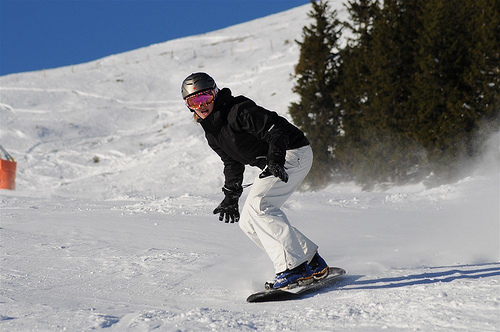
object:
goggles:
[186, 87, 215, 109]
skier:
[179, 71, 346, 303]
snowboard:
[244, 266, 345, 303]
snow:
[2, 2, 499, 329]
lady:
[180, 72, 328, 291]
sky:
[1, 0, 241, 61]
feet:
[265, 270, 315, 290]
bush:
[290, 0, 500, 192]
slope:
[2, 0, 497, 328]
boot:
[264, 261, 312, 290]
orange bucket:
[1, 143, 16, 191]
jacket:
[195, 88, 310, 197]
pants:
[236, 142, 320, 275]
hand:
[213, 203, 241, 223]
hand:
[258, 165, 289, 183]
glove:
[212, 191, 240, 224]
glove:
[259, 156, 288, 183]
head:
[181, 72, 220, 120]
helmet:
[181, 72, 217, 99]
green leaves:
[321, 39, 466, 149]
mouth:
[201, 109, 209, 115]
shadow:
[341, 261, 499, 291]